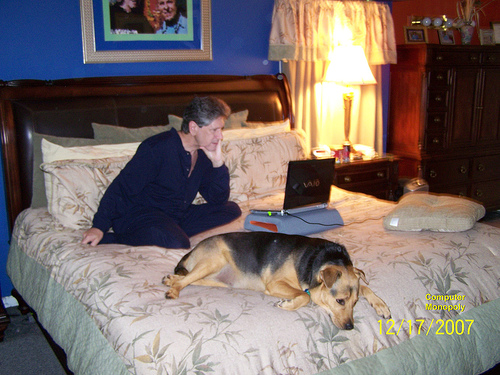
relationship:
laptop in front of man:
[252, 156, 333, 216] [81, 91, 248, 251]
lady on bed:
[81, 91, 248, 251] [11, 174, 497, 374]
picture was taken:
[4, 1, 498, 373] [383, 291, 482, 339]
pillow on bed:
[214, 127, 308, 203] [11, 174, 497, 374]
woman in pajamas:
[81, 91, 248, 251] [84, 129, 227, 219]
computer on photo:
[425, 291, 465, 304] [4, 1, 498, 373]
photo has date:
[4, 1, 498, 373] [376, 313, 479, 344]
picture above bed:
[76, 0, 216, 61] [11, 174, 497, 374]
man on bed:
[81, 91, 248, 251] [11, 174, 497, 374]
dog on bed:
[166, 224, 397, 333] [11, 174, 497, 374]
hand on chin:
[206, 139, 222, 165] [197, 136, 220, 149]